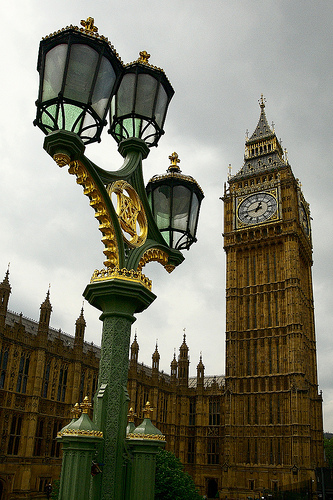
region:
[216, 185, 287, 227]
The clock is gold and black.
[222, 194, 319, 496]
The tower is tall.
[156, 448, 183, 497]
The bush is leafy.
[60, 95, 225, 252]
Three lights on the pole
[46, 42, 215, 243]
The lights are off.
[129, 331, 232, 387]
The pillars are tall.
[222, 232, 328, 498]
The building is brown.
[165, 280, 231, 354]
the sky is cloudy and overcast.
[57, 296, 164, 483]
The pole is green.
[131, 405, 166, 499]
The crosses are gold.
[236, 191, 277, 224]
ornate clock face with black hands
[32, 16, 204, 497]
ornate green black and gold lamp post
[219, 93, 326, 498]
Brown Big Ben clock tower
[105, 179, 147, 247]
gold coat of arms in a gold circle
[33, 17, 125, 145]
black glass and metal lamp with gold decoration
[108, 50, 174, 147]
black metal and glass lamp with gold decoration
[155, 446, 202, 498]
green leafy tree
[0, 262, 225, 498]
brown pointy spires atop the parliament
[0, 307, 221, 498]
grey roof of parliament building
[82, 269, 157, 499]
green central pillar of lamp post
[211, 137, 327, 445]
very old clock tower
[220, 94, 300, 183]
crosses on the clock tower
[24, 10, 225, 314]
old fashioned lighting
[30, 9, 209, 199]
grosses on the lights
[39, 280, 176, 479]
green poles holding lights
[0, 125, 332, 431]
old church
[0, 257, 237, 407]
spires on the church building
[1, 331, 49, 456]
very long windows on the building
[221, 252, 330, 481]
old style clock tower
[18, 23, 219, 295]
lamps reaching into the gray sky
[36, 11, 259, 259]
The light has three bulbs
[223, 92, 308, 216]
steeple on top of building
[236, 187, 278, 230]
Clock on front of building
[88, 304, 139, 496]
Green pole with decoration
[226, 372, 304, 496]
Tall windows on building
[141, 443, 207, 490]
Green bush beside building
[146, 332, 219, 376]
Steeples on top of building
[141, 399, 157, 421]
Gold decorative top on pole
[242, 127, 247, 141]
Points on top of steeple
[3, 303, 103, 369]
roof has spikes on top of it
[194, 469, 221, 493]
a door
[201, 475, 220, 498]
a door